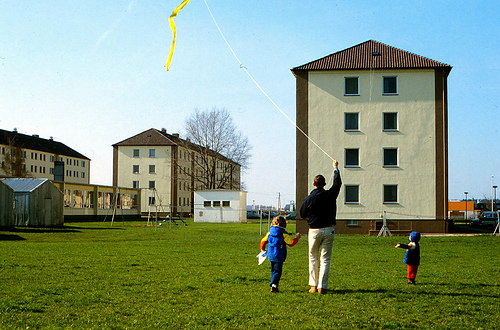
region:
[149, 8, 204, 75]
yellow kite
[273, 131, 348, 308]
man flying kite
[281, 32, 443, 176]
brown and white building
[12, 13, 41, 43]
white clouds in blue sky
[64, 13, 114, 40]
white clouds in blue sky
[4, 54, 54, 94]
white clouds in blue sky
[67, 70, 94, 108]
white clouds in blue sky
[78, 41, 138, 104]
white clouds in blue sky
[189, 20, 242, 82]
white clouds in blue sky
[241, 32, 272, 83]
white clouds in blue sky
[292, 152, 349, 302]
man holding a kite string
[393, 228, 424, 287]
toddler in the grass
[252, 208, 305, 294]
young child by a man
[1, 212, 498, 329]
green grassy area behind buildings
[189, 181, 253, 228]
small white shed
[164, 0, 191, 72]
yellow kite tail in the sky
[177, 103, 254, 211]
tree with bare branches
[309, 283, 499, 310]
shadow of a man on the grass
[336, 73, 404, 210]
eight windows on the nearest building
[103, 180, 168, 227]
swing set in the yard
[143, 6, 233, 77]
a yellow kite in the sky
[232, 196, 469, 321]
two kids in the grass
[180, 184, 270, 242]
a short white building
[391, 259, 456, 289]
red pants on child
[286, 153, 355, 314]
a man in black jacket and white pants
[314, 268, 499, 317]
shadows on ground from man and child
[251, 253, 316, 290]
blue pants on child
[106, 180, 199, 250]
a swing set for children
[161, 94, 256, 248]
a tree with no leaves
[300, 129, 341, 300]
Man holding a string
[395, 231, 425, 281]
Young boy wearing red pants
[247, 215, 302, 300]
Child wearing blue pants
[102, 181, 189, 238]
Swing set on grass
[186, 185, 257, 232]
Small white shack on grass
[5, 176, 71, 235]
Silver shed on grass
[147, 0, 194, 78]
Yellow kite in sky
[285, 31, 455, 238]
Building in front of man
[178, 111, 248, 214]
Tree with no leaves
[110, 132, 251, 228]
Building behind the tree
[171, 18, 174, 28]
The tail of a kite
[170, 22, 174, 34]
Yellow tail of kite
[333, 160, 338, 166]
Hand raised up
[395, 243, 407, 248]
Arm extended outwards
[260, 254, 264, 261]
A piece of paper in the hand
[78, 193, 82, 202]
Reflection on the window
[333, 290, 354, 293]
Shadow from the man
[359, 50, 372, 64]
Brown roof on the building